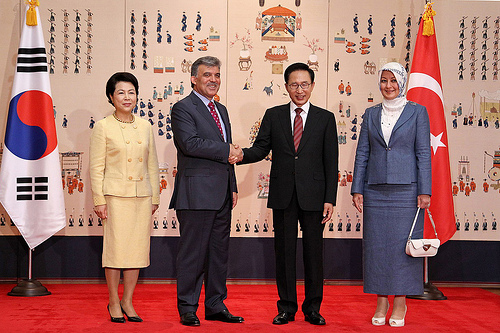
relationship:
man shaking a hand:
[168, 56, 243, 326] [228, 144, 240, 164]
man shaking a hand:
[228, 52, 339, 325] [228, 143, 244, 163]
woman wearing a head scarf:
[351, 62, 432, 327] [378, 62, 408, 98]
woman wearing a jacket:
[351, 62, 432, 327] [351, 100, 432, 197]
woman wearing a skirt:
[351, 62, 432, 327] [363, 182, 424, 295]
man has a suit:
[228, 52, 339, 325] [236, 101, 338, 314]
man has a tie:
[228, 52, 339, 325] [294, 108, 304, 152]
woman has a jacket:
[90, 72, 161, 323] [89, 113, 160, 207]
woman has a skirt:
[90, 72, 161, 323] [101, 195, 152, 268]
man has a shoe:
[228, 52, 339, 325] [304, 311, 326, 326]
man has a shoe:
[228, 52, 339, 325] [272, 311, 295, 325]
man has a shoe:
[168, 56, 243, 326] [205, 309, 244, 323]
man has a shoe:
[168, 56, 243, 326] [180, 312, 200, 327]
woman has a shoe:
[351, 62, 432, 327] [389, 304, 408, 327]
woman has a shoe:
[351, 62, 432, 327] [371, 300, 389, 325]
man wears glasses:
[228, 52, 339, 325] [286, 82, 314, 91]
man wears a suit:
[228, 52, 339, 325] [236, 101, 338, 314]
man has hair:
[168, 56, 243, 326] [191, 56, 222, 89]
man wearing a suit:
[168, 56, 243, 326] [169, 90, 238, 316]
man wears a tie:
[228, 52, 339, 325] [294, 108, 304, 152]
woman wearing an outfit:
[90, 72, 161, 323] [90, 113, 160, 269]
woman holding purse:
[351, 62, 432, 327] [405, 207, 441, 258]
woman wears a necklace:
[90, 72, 161, 323] [112, 110, 135, 124]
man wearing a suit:
[228, 52, 339, 325] [236, 101, 338, 314]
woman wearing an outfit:
[351, 62, 432, 327] [351, 101, 432, 296]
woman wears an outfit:
[90, 72, 161, 323] [90, 113, 160, 269]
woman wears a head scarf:
[351, 62, 432, 327] [378, 62, 408, 98]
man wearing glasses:
[228, 52, 339, 325] [286, 82, 314, 91]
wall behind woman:
[0, 0, 500, 284] [90, 72, 161, 323]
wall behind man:
[0, 0, 500, 284] [168, 56, 243, 326]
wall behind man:
[0, 0, 500, 284] [228, 52, 339, 325]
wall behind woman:
[0, 0, 500, 284] [351, 62, 432, 327]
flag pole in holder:
[28, 248, 33, 279] [7, 277, 51, 296]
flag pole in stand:
[423, 256, 429, 284] [405, 284, 447, 301]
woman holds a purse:
[351, 62, 432, 327] [405, 207, 441, 258]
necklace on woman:
[112, 110, 135, 124] [90, 72, 161, 323]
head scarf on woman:
[378, 62, 408, 98] [351, 62, 432, 327]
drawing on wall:
[255, 4, 303, 44] [0, 0, 500, 284]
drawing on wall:
[230, 27, 254, 70] [0, 0, 500, 284]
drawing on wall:
[302, 35, 324, 71] [0, 0, 500, 284]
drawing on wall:
[264, 45, 289, 64] [0, 0, 500, 284]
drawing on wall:
[243, 71, 253, 91] [0, 0, 500, 284]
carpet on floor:
[0, 283, 499, 332] [0, 280, 499, 332]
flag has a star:
[406, 16, 457, 245] [429, 132, 447, 155]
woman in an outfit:
[90, 72, 161, 323] [90, 113, 160, 269]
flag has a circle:
[0, 6, 66, 250] [4, 90, 57, 161]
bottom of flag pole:
[5, 279, 53, 297] [28, 248, 33, 279]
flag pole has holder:
[28, 248, 33, 279] [24, 277, 34, 283]